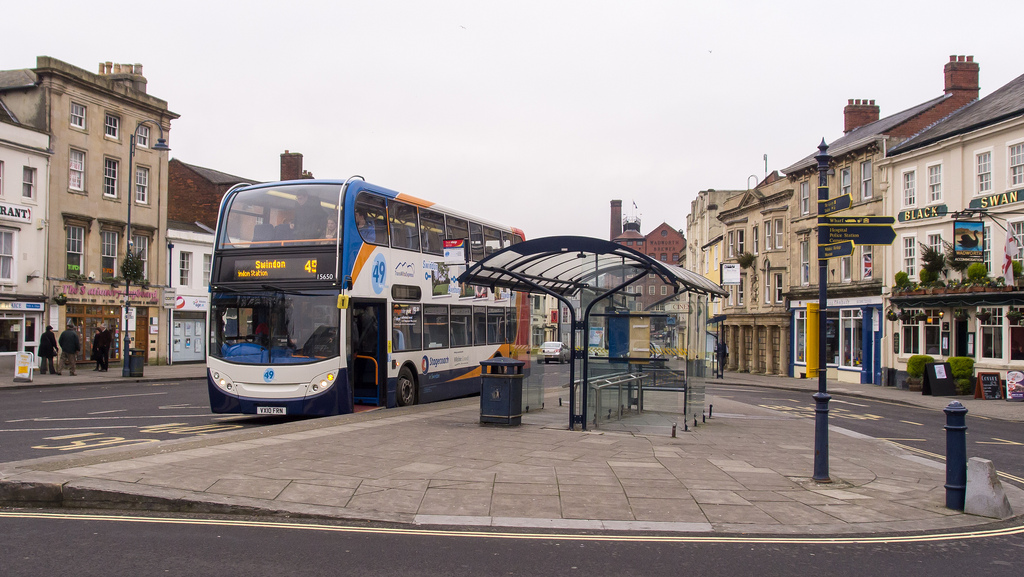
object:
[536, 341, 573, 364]
silver car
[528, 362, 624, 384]
road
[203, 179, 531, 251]
top level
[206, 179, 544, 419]
bus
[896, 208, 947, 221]
sign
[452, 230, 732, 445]
bus-waiting area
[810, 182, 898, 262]
street sign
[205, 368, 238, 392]
bus headlights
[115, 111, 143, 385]
tall-light pole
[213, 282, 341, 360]
bus-front window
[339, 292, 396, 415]
bus door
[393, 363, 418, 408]
bus wheel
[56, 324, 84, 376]
people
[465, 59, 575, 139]
thick clouds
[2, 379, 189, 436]
dark-grey road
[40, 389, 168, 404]
white lines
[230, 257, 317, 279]
orange lcd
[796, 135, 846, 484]
black pole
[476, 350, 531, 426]
black-trash can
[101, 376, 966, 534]
ground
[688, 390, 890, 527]
sidewalk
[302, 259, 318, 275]
orange-bus numbers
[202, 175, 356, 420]
bus front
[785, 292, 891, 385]
building paint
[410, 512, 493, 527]
white-painted blocks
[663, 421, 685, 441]
small-black stands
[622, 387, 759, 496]
ground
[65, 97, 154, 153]
three windows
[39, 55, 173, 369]
building front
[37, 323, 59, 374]
people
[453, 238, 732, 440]
bus stop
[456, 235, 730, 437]
shelter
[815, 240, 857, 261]
sign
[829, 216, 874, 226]
street name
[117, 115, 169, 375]
street light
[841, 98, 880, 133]
chimney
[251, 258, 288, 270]
destination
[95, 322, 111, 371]
person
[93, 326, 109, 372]
person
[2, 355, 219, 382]
sidewalk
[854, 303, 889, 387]
trim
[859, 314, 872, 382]
door